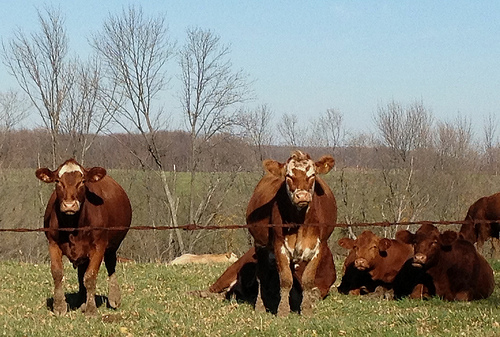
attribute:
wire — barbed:
[151, 217, 234, 237]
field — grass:
[138, 271, 187, 331]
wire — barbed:
[143, 214, 244, 238]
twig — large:
[182, 188, 215, 229]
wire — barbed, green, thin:
[7, 211, 492, 239]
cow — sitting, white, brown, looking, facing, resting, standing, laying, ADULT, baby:
[13, 141, 498, 315]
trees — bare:
[7, 4, 498, 242]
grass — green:
[5, 259, 498, 329]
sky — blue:
[2, 5, 498, 147]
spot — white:
[57, 163, 81, 177]